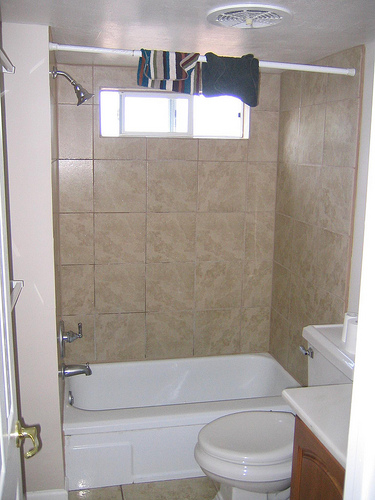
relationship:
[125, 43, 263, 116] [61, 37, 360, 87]
towel on rod